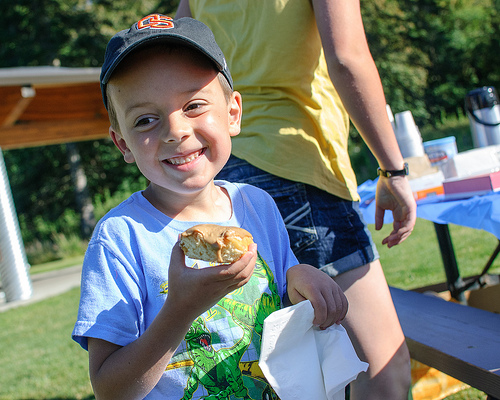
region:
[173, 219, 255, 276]
donut with frosting missing a bite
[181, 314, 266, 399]
green dinosaur on powder blue shirt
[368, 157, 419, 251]
right hand with watch on wrist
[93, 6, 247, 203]
young boy smiling with baseball cap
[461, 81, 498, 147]
silver and black plastic thermos on table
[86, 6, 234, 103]
dark blue baseball cap with orange logo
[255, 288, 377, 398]
white paper napkin in left hand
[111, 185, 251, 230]
collar of light blue tee shirt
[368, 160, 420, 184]
black leather thin watch band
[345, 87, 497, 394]
food and beverages on a picnic table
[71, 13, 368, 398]
Child is happy about his treat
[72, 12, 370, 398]
Child holds dessert in his hand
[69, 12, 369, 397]
Child holds napkin in his hand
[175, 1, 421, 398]
person in background is wearing shorts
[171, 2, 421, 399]
person in background is wearing a watch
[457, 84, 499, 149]
Container holds coffee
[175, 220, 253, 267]
Donut is nearly half-eaten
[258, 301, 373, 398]
Napkin is fairly clean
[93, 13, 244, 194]
Hat sits on head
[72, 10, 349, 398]
Boy wears shirt with dinosaur on it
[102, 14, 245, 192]
smiling face of a boy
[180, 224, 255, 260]
partially eaten pastry in boy's hand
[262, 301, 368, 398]
paper napkin in boy's hand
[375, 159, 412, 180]
watch on a right wrist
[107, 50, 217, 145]
shadow of the bill of the cap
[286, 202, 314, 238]
white stripes on pants pocket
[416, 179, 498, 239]
blue water of a pool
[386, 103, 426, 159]
stacks of paper cups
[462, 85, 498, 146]
a thermos with a handle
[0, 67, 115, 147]
a roof for shade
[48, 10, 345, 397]
boy has a sandwich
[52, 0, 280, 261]
boy has a blue cap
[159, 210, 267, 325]
hand in a sandwich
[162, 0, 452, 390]
man wears a yellow top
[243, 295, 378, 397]
a white napkin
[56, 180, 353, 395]
a shirt is blue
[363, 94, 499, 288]
a table with blue cover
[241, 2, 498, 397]
a bench in front a woman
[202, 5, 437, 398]
woman wears blue short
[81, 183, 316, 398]
shirt with green designs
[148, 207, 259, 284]
the doughnut in the hand of the child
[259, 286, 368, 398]
a white napkin in the childs hand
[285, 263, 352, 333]
the hand of the boy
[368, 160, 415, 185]
the watch on the womens wrist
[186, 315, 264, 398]
a green dinosaur on the tee shirt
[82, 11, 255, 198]
the boy with a smile on his face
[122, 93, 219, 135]
the eyes of the child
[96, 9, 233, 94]
the hat on the boys head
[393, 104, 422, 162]
the stack of cups on the table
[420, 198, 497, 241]
the blue table cloth on the table